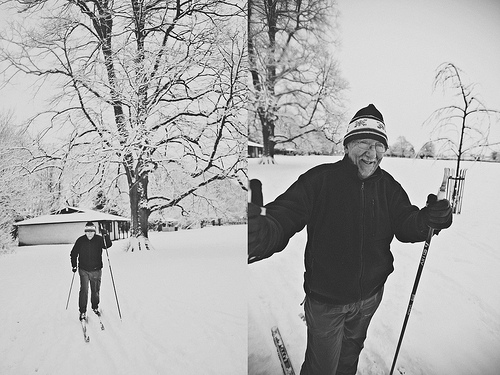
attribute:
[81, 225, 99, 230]
balaclava — white 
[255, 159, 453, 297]
fleece jacket — black 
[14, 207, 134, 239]
house — white 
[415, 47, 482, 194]
tree — Small 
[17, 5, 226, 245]
tree — snow covered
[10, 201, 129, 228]
roof — snow covered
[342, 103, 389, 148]
marvin — white 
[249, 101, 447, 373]
man — smiling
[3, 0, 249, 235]
barren tree — Tall 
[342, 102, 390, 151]
hat — Striped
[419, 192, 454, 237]
glove — black 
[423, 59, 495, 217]
tree — scrawny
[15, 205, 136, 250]
house — single story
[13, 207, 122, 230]
roof — snow covered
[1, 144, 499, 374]
landscape — snow covered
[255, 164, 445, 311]
sweater — black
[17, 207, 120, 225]
roof — snow covered